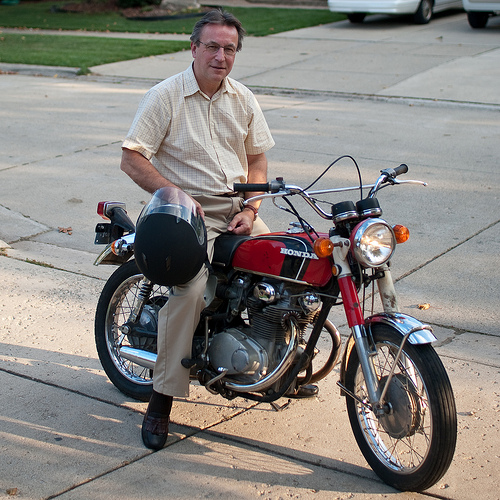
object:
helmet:
[132, 184, 211, 291]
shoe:
[141, 394, 171, 453]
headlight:
[352, 218, 396, 268]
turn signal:
[392, 222, 411, 244]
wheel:
[343, 313, 459, 493]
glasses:
[196, 40, 240, 55]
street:
[0, 65, 499, 341]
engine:
[238, 272, 323, 368]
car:
[326, 0, 470, 25]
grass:
[2, 1, 346, 69]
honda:
[279, 240, 324, 263]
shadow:
[0, 340, 391, 497]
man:
[118, 9, 277, 452]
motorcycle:
[83, 150, 460, 496]